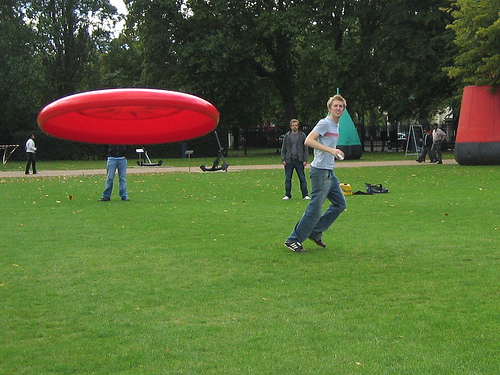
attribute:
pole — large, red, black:
[449, 77, 486, 169]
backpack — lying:
[359, 177, 389, 197]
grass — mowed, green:
[5, 156, 497, 372]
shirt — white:
[23, 139, 38, 153]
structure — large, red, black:
[452, 80, 497, 163]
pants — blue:
[282, 162, 348, 244]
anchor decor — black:
[194, 144, 234, 172]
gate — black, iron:
[358, 123, 404, 150]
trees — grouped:
[119, 0, 414, 155]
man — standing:
[268, 97, 308, 206]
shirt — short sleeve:
[309, 115, 339, 171]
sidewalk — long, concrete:
[13, 153, 453, 190]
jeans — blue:
[298, 147, 436, 319]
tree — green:
[97, 0, 307, 121]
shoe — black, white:
[280, 237, 306, 256]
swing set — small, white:
[403, 124, 426, 159]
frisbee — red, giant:
[51, 86, 221, 153]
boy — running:
[285, 94, 349, 250]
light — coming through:
[89, 1, 132, 41]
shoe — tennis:
[240, 224, 324, 265]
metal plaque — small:
[181, 146, 198, 158]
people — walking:
[217, 54, 398, 290]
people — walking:
[413, 121, 448, 165]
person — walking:
[20, 133, 43, 175]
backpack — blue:
[341, 163, 406, 208]